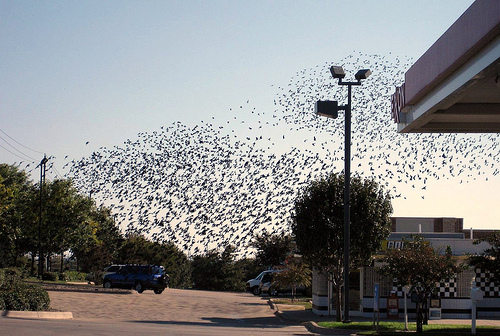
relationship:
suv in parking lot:
[96, 260, 170, 290] [0, 270, 303, 334]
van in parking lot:
[247, 272, 271, 292] [0, 270, 303, 334]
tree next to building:
[282, 164, 376, 324] [381, 204, 496, 265]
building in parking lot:
[367, 224, 496, 283] [4, 252, 493, 333]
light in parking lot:
[319, 66, 370, 189] [16, 267, 497, 334]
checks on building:
[425, 260, 495, 295] [370, 256, 498, 302]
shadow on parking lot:
[123, 301, 310, 327] [19, 275, 321, 328]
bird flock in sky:
[53, 51, 497, 254] [6, 4, 496, 242]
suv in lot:
[98, 263, 170, 295] [0, 273, 499, 333]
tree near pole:
[291, 163, 393, 325] [333, 73, 354, 176]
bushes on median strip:
[8, 280, 56, 310] [0, 304, 74, 324]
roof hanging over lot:
[385, 0, 495, 140] [0, 273, 499, 333]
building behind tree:
[367, 224, 496, 283] [278, 168, 398, 320]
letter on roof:
[385, 82, 403, 124] [385, 3, 498, 149]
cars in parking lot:
[242, 261, 292, 311] [17, 267, 324, 331]